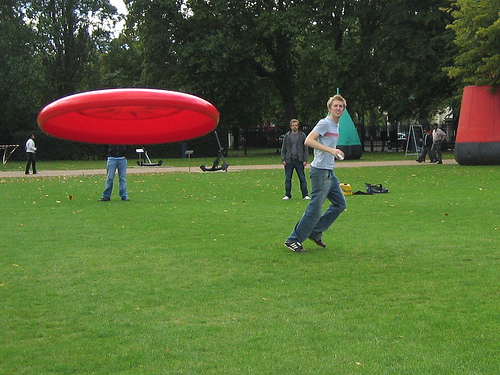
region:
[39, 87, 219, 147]
Circular red plastic frisbee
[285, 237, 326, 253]
Pair of black and white shoes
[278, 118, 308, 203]
Man wearing jacket standing in background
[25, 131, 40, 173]
Person wearing white shirt walking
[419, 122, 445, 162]
Group of people walking on sidewalk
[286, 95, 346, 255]
Boy in grey shirt throwing frisbee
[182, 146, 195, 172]
Small metal plack with pole in ground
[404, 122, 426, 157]
Small white swing set in background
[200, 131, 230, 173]
Black anchor decor on sidewalk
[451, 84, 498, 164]
Red and black inflatable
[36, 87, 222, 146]
a flying red frisbee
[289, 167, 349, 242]
a pair of blue jeans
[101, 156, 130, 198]
a pair of blue jeans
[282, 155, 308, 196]
a pair of blue jeans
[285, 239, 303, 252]
a black and white shoe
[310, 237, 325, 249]
a black and white shoe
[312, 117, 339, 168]
a men's grey t-shirt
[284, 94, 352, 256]
a young man running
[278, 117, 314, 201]
a man standing in field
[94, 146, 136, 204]
a man standing in field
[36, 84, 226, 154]
A giant red frisbee.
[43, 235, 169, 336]
Well-maintained green grass.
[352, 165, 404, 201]
A blue backpack on the grass.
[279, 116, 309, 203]
A man standing on the grass.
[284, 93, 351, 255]
A boy running across the grass.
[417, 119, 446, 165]
Two people walking on the side walk.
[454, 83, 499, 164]
A large red and black structure.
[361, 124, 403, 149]
A black iron gate.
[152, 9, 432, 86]
A large group of trees.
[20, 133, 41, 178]
A person walking east.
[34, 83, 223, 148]
A red frisbee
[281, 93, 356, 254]
A blonde guy in blue jeans running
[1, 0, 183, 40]
Light coming through some trees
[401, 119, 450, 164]
Two people walking on a sidewalk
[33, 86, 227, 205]
Person whose upper body is blocked out by a frisbee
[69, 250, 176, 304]
Small patch of mowed green grass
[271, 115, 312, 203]
Expressionless man with a beard standing in the grass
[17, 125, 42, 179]
Woman in a white sweater and black pants taking a walk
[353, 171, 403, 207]
Backpack lying in the grass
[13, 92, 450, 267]
People doing various activities in a park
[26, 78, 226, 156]
a large red Frisbee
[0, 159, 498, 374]
a large green area of grass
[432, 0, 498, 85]
part of a green tree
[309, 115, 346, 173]
a man' short sleeve shirt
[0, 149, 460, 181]
a long concrete sidewalk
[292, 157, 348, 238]
a man's blue jean pants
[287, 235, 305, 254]
a man's tennis shoe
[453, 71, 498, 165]
a large red and black pole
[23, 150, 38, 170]
a man's black jeans